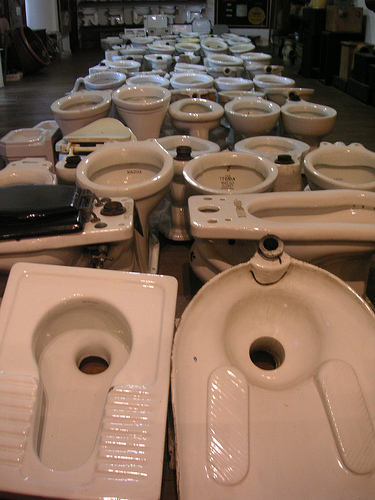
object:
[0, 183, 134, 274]
toilet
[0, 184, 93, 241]
lid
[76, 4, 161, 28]
toilet bowls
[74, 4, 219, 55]
wall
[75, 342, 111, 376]
hole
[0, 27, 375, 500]
toilet bowl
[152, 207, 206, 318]
floor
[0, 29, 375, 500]
toilets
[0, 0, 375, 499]
room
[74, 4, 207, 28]
toilets